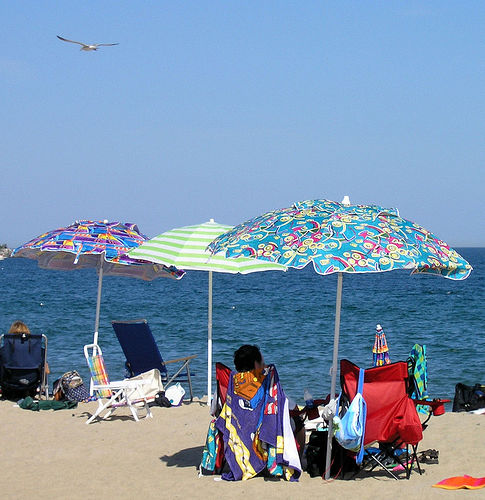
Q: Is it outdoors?
A: Yes, it is outdoors.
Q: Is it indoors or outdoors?
A: It is outdoors.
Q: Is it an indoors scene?
A: No, it is outdoors.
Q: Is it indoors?
A: No, it is outdoors.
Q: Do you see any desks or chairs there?
A: Yes, there is a chair.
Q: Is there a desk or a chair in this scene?
A: Yes, there is a chair.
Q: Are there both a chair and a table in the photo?
A: No, there is a chair but no tables.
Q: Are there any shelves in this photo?
A: No, there are no shelves.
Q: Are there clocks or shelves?
A: No, there are no shelves or clocks.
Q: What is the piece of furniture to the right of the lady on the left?
A: The piece of furniture is a chair.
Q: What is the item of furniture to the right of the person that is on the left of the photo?
A: The piece of furniture is a chair.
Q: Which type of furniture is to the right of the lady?
A: The piece of furniture is a chair.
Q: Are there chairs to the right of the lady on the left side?
A: Yes, there is a chair to the right of the lady.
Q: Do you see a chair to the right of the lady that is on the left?
A: Yes, there is a chair to the right of the lady.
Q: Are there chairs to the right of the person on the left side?
A: Yes, there is a chair to the right of the lady.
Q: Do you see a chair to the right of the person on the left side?
A: Yes, there is a chair to the right of the lady.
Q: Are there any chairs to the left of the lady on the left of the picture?
A: No, the chair is to the right of the lady.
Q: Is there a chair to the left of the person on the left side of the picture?
A: No, the chair is to the right of the lady.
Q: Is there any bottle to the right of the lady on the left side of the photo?
A: No, there is a chair to the right of the lady.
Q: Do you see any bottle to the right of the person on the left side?
A: No, there is a chair to the right of the lady.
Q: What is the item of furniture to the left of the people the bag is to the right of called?
A: The piece of furniture is a chair.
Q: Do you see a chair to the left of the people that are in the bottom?
A: Yes, there is a chair to the left of the people.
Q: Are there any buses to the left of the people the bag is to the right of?
A: No, there is a chair to the left of the people.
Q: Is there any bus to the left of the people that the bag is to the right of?
A: No, there is a chair to the left of the people.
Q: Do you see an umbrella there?
A: Yes, there is an umbrella.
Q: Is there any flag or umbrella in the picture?
A: Yes, there is an umbrella.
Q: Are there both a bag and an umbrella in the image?
A: Yes, there are both an umbrella and a bag.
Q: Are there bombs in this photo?
A: No, there are no bombs.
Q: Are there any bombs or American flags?
A: No, there are no bombs or American flags.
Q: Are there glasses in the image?
A: No, there are no glasses.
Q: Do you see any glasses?
A: No, there are no glasses.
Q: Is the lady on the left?
A: Yes, the lady is on the left of the image.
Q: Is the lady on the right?
A: No, the lady is on the left of the image.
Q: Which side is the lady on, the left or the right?
A: The lady is on the left of the image.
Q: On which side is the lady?
A: The lady is on the left of the image.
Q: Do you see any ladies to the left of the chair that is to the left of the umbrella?
A: Yes, there is a lady to the left of the chair.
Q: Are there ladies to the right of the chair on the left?
A: No, the lady is to the left of the chair.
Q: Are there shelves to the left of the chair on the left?
A: No, there is a lady to the left of the chair.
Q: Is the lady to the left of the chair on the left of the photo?
A: Yes, the lady is to the left of the chair.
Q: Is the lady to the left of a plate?
A: No, the lady is to the left of the chair.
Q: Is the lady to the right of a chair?
A: No, the lady is to the left of a chair.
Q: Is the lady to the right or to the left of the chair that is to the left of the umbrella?
A: The lady is to the left of the chair.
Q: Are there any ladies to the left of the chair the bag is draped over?
A: Yes, there is a lady to the left of the chair.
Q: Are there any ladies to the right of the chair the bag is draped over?
A: No, the lady is to the left of the chair.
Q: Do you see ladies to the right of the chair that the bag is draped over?
A: No, the lady is to the left of the chair.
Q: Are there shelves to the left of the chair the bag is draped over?
A: No, there is a lady to the left of the chair.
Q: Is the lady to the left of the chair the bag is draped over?
A: Yes, the lady is to the left of the chair.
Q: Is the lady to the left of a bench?
A: No, the lady is to the left of the chair.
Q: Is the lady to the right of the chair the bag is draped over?
A: No, the lady is to the left of the chair.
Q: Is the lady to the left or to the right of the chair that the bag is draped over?
A: The lady is to the left of the chair.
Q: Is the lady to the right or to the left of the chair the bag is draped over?
A: The lady is to the left of the chair.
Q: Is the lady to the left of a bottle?
A: No, the lady is to the left of the umbrella.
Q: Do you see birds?
A: Yes, there is a bird.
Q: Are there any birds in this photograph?
A: Yes, there is a bird.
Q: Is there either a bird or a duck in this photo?
A: Yes, there is a bird.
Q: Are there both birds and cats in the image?
A: No, there is a bird but no cats.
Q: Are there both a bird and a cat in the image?
A: No, there is a bird but no cats.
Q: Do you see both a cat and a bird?
A: No, there is a bird but no cats.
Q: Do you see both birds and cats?
A: No, there is a bird but no cats.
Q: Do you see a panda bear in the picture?
A: No, there are no panda bears.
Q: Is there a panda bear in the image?
A: No, there are no panda bears.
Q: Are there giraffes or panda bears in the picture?
A: No, there are no panda bears or giraffes.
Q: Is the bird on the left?
A: Yes, the bird is on the left of the image.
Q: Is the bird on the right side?
A: No, the bird is on the left of the image.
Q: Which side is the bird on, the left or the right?
A: The bird is on the left of the image.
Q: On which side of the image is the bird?
A: The bird is on the left of the image.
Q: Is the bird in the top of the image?
A: Yes, the bird is in the top of the image.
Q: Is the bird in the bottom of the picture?
A: No, the bird is in the top of the image.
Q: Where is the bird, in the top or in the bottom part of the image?
A: The bird is in the top of the image.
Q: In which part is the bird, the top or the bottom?
A: The bird is in the top of the image.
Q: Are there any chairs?
A: Yes, there is a chair.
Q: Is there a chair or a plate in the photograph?
A: Yes, there is a chair.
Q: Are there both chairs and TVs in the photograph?
A: No, there is a chair but no televisions.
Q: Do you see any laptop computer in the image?
A: No, there are no laptops.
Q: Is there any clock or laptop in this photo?
A: No, there are no laptops or clocks.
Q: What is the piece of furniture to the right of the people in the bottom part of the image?
A: The piece of furniture is a chair.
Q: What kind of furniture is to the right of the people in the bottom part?
A: The piece of furniture is a chair.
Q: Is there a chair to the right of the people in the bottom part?
A: Yes, there is a chair to the right of the people.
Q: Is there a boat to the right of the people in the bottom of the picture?
A: No, there is a chair to the right of the people.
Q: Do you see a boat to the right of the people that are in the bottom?
A: No, there is a chair to the right of the people.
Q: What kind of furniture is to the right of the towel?
A: The piece of furniture is a chair.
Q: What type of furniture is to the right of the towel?
A: The piece of furniture is a chair.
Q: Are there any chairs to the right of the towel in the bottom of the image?
A: Yes, there is a chair to the right of the towel.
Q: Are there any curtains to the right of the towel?
A: No, there is a chair to the right of the towel.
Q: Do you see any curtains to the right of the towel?
A: No, there is a chair to the right of the towel.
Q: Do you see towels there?
A: Yes, there is a towel.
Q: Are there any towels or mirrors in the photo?
A: Yes, there is a towel.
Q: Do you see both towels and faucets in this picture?
A: No, there is a towel but no faucets.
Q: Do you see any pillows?
A: No, there are no pillows.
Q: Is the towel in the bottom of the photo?
A: Yes, the towel is in the bottom of the image.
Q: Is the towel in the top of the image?
A: No, the towel is in the bottom of the image.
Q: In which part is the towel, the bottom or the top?
A: The towel is in the bottom of the image.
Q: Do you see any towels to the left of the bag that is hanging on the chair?
A: Yes, there is a towel to the left of the bag.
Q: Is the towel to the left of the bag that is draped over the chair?
A: Yes, the towel is to the left of the bag.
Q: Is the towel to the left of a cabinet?
A: No, the towel is to the left of the bag.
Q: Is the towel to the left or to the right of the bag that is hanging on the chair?
A: The towel is to the left of the bag.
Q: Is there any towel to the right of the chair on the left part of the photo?
A: Yes, there is a towel to the right of the chair.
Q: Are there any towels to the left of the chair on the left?
A: No, the towel is to the right of the chair.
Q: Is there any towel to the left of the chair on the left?
A: No, the towel is to the right of the chair.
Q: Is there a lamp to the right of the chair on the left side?
A: No, there is a towel to the right of the chair.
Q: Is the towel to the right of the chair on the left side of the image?
A: Yes, the towel is to the right of the chair.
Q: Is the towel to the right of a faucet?
A: No, the towel is to the right of the chair.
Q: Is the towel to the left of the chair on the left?
A: No, the towel is to the right of the chair.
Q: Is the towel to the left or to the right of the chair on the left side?
A: The towel is to the right of the chair.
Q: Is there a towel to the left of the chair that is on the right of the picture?
A: Yes, there is a towel to the left of the chair.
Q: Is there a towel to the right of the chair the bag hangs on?
A: No, the towel is to the left of the chair.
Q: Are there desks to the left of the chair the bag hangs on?
A: No, there is a towel to the left of the chair.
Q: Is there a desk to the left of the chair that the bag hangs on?
A: No, there is a towel to the left of the chair.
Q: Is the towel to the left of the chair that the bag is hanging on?
A: Yes, the towel is to the left of the chair.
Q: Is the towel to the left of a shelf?
A: No, the towel is to the left of the chair.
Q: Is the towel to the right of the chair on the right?
A: No, the towel is to the left of the chair.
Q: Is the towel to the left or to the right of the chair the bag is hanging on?
A: The towel is to the left of the chair.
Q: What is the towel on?
A: The towel is on the chair.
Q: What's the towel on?
A: The towel is on the chair.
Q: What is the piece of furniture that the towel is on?
A: The piece of furniture is a chair.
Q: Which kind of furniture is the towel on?
A: The towel is on the chair.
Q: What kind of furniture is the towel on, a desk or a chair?
A: The towel is on a chair.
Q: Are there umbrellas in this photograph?
A: Yes, there is an umbrella.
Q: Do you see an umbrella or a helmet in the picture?
A: Yes, there is an umbrella.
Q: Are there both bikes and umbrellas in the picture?
A: No, there is an umbrella but no bikes.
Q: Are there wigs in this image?
A: No, there are no wigs.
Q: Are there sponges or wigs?
A: No, there are no wigs or sponges.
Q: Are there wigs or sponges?
A: No, there are no wigs or sponges.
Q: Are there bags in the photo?
A: Yes, there is a bag.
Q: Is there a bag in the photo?
A: Yes, there is a bag.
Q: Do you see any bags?
A: Yes, there is a bag.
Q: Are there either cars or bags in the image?
A: Yes, there is a bag.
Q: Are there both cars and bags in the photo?
A: No, there is a bag but no cars.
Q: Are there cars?
A: No, there are no cars.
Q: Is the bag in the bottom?
A: Yes, the bag is in the bottom of the image.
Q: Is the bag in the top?
A: No, the bag is in the bottom of the image.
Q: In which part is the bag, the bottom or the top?
A: The bag is in the bottom of the image.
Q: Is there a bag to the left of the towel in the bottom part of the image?
A: No, the bag is to the right of the towel.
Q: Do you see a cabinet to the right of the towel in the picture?
A: No, there is a bag to the right of the towel.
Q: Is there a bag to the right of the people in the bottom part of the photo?
A: Yes, there is a bag to the right of the people.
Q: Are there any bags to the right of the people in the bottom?
A: Yes, there is a bag to the right of the people.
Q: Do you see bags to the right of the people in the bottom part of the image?
A: Yes, there is a bag to the right of the people.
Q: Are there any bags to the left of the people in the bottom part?
A: No, the bag is to the right of the people.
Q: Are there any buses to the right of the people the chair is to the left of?
A: No, there is a bag to the right of the people.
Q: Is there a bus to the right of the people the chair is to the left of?
A: No, there is a bag to the right of the people.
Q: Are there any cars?
A: No, there are no cars.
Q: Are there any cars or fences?
A: No, there are no cars or fences.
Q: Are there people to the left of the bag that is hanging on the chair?
A: Yes, there are people to the left of the bag.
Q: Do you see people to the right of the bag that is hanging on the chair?
A: No, the people are to the left of the bag.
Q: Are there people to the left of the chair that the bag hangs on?
A: Yes, there are people to the left of the chair.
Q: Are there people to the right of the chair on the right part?
A: No, the people are to the left of the chair.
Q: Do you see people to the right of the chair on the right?
A: No, the people are to the left of the chair.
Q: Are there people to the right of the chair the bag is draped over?
A: Yes, there are people to the right of the chair.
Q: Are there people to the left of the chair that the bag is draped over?
A: No, the people are to the right of the chair.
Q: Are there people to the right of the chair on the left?
A: Yes, there are people to the right of the chair.